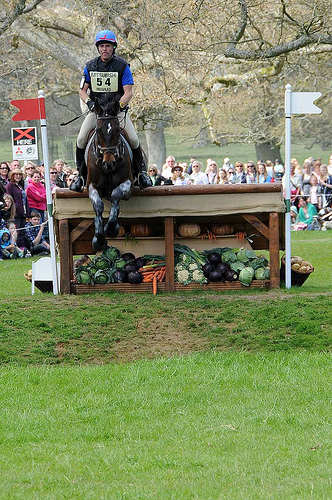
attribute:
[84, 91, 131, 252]
horse — brown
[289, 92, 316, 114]
flag — white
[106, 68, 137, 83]
shirt — blue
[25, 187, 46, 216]
shirt — pink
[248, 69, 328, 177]
flag — white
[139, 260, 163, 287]
carrots — orange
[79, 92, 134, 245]
horse — jumping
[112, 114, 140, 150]
pants — tan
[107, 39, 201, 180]
tree — bare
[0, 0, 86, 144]
tree — bare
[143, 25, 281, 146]
tree — bare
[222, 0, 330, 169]
tree — bare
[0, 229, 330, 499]
grass — green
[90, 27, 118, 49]
helmet — blue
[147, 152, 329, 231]
crowd — people